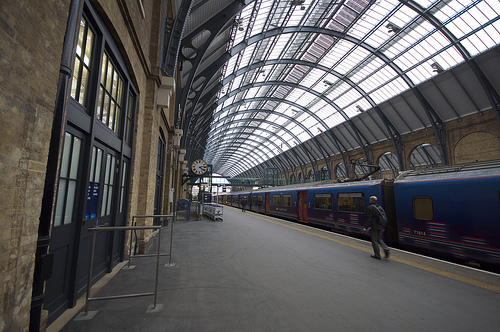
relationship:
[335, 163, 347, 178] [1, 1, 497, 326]
window on building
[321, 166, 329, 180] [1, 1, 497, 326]
window on building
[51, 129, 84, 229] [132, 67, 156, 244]
window on building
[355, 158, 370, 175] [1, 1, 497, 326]
window on building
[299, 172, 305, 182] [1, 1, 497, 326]
window on building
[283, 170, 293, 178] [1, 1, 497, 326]
window on building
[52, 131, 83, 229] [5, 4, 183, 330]
window on building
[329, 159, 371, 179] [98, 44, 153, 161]
window on building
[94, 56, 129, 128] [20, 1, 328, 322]
window on building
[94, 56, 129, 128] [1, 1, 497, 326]
window on building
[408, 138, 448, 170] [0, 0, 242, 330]
window on building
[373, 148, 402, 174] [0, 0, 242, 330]
window on building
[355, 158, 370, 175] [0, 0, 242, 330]
window on building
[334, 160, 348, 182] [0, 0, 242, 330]
window on building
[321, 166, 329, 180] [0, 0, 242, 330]
window on building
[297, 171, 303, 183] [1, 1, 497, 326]
window on building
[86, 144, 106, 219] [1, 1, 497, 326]
window on building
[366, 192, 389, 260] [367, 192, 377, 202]
man with head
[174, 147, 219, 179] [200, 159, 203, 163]
clock with roman numerals